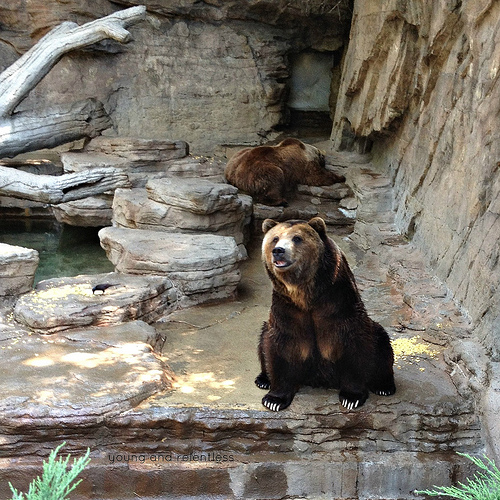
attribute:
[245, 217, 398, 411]
bear — sitting, sleeping, alert, sitting up, brown, dark brown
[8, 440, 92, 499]
plant — green, pine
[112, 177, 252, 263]
stone — large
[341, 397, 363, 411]
claws — white, long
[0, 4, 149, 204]
wood — large, old tree branch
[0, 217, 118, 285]
water — pool for bears, clear, blue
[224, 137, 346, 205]
bear — sleeping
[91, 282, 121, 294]
bird — standing, eating, black